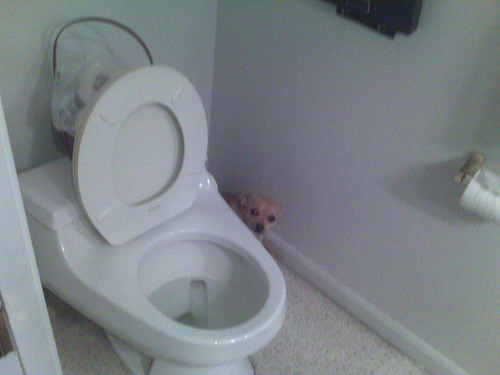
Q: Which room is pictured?
A: It is a bathroom.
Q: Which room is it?
A: It is a bathroom.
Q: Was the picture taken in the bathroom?
A: Yes, it was taken in the bathroom.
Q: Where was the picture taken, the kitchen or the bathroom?
A: It was taken at the bathroom.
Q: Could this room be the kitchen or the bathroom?
A: It is the bathroom.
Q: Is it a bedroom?
A: No, it is a bathroom.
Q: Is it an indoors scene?
A: Yes, it is indoors.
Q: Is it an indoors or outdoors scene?
A: It is indoors.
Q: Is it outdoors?
A: No, it is indoors.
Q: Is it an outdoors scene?
A: No, it is indoors.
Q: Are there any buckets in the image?
A: No, there are no buckets.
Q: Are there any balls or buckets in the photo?
A: No, there are no buckets or balls.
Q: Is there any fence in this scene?
A: No, there are no fences.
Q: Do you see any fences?
A: No, there are no fences.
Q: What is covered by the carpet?
A: The ground is covered by the carpet.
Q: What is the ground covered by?
A: The ground is covered by the carpet.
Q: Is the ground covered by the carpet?
A: Yes, the ground is covered by the carpet.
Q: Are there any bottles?
A: No, there are no bottles.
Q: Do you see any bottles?
A: No, there are no bottles.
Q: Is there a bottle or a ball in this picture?
A: No, there are no bottles or balls.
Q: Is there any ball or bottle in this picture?
A: No, there are no bottles or balls.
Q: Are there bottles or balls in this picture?
A: No, there are no bottles or balls.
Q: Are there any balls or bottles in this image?
A: No, there are no bottles or balls.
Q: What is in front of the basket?
A: The toilet is in front of the basket.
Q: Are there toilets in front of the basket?
A: Yes, there is a toilet in front of the basket.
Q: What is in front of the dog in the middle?
A: The toilet is in front of the dog.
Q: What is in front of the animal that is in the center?
A: The toilet is in front of the dog.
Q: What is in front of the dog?
A: The toilet is in front of the dog.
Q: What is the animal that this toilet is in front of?
A: The animal is a dog.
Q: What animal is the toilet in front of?
A: The toilet is in front of the dog.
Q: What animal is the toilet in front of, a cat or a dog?
A: The toilet is in front of a dog.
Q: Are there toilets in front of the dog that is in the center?
A: Yes, there is a toilet in front of the dog.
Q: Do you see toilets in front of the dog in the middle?
A: Yes, there is a toilet in front of the dog.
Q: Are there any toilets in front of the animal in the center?
A: Yes, there is a toilet in front of the dog.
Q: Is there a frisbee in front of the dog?
A: No, there is a toilet in front of the dog.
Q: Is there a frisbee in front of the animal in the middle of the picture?
A: No, there is a toilet in front of the dog.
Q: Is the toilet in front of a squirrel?
A: No, the toilet is in front of a dog.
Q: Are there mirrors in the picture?
A: No, there are no mirrors.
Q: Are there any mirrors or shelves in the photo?
A: No, there are no mirrors or shelves.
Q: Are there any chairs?
A: No, there are no chairs.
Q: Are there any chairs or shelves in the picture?
A: No, there are no chairs or shelves.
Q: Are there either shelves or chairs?
A: No, there are no chairs or shelves.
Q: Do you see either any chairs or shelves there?
A: No, there are no chairs or shelves.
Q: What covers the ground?
A: The carpet covers the ground.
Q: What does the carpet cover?
A: The carpet covers the ground.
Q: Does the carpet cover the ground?
A: Yes, the carpet covers the ground.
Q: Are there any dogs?
A: Yes, there is a dog.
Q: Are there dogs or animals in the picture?
A: Yes, there is a dog.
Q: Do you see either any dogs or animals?
A: Yes, there is a dog.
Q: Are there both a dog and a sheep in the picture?
A: No, there is a dog but no sheep.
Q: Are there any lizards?
A: No, there are no lizards.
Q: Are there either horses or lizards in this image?
A: No, there are no lizards or horses.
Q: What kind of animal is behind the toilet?
A: The animal is a dog.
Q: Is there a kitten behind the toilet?
A: No, there is a dog behind the toilet.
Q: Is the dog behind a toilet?
A: Yes, the dog is behind a toilet.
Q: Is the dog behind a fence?
A: No, the dog is behind a toilet.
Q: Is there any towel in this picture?
A: No, there are no towels.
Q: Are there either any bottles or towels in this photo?
A: No, there are no towels or bottles.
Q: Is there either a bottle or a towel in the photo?
A: No, there are no towels or bottles.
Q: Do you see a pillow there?
A: No, there are no pillows.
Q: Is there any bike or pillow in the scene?
A: No, there are no pillows or bikes.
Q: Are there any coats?
A: Yes, there is a coat.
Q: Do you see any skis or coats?
A: Yes, there is a coat.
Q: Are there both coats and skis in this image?
A: No, there is a coat but no skis.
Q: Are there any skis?
A: No, there are no skis.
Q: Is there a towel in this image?
A: No, there are no towels.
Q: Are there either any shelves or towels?
A: No, there are no towels or shelves.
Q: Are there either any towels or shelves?
A: No, there are no towels or shelves.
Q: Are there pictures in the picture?
A: No, there are no pictures.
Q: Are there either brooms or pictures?
A: No, there are no pictures or brooms.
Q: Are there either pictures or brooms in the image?
A: No, there are no pictures or brooms.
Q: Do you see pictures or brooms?
A: No, there are no pictures or brooms.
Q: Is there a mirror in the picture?
A: No, there are no mirrors.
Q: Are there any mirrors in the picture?
A: No, there are no mirrors.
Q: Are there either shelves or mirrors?
A: No, there are no mirrors or shelves.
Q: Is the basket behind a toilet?
A: Yes, the basket is behind a toilet.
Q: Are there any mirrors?
A: No, there are no mirrors.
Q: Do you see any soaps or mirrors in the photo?
A: No, there are no mirrors or soaps.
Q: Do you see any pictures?
A: No, there are no pictures.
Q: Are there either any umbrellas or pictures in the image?
A: No, there are no pictures or umbrellas.